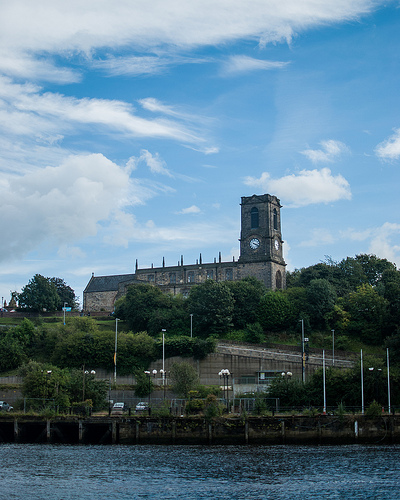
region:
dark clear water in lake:
[159, 452, 306, 498]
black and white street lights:
[212, 364, 236, 420]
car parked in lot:
[108, 397, 128, 412]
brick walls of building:
[252, 258, 269, 274]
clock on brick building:
[245, 232, 266, 257]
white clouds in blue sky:
[51, 100, 158, 212]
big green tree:
[14, 272, 79, 322]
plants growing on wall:
[96, 345, 140, 390]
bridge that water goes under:
[37, 418, 126, 472]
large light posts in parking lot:
[293, 309, 315, 412]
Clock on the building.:
[243, 232, 264, 252]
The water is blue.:
[63, 453, 363, 497]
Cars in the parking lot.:
[103, 394, 165, 414]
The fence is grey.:
[27, 392, 281, 415]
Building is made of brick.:
[80, 194, 302, 303]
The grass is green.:
[8, 312, 127, 333]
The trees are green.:
[132, 264, 394, 341]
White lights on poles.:
[212, 365, 236, 381]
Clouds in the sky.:
[20, 162, 119, 257]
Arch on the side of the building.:
[271, 267, 287, 293]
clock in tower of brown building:
[243, 235, 264, 253]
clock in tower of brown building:
[266, 238, 283, 256]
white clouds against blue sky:
[10, 5, 86, 66]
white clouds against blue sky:
[10, 96, 98, 146]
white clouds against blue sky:
[24, 209, 131, 257]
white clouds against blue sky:
[118, 194, 202, 244]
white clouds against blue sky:
[305, 184, 370, 244]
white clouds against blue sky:
[119, 165, 208, 208]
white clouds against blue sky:
[91, 44, 231, 125]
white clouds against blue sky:
[196, 28, 366, 109]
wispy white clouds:
[0, 1, 398, 67]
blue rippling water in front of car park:
[1, 441, 398, 498]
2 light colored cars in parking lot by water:
[112, 399, 149, 412]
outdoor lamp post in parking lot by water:
[216, 368, 237, 412]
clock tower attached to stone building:
[239, 197, 283, 263]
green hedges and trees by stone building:
[127, 283, 396, 325]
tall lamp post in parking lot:
[162, 327, 166, 402]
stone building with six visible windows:
[84, 256, 285, 308]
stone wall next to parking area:
[154, 355, 320, 382]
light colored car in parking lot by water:
[0, 397, 14, 409]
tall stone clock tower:
[237, 189, 285, 272]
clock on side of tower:
[241, 231, 266, 258]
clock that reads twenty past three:
[244, 232, 263, 254]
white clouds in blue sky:
[2, 83, 392, 279]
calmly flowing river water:
[5, 423, 397, 499]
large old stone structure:
[64, 189, 309, 318]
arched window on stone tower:
[247, 204, 263, 233]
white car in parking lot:
[133, 397, 153, 416]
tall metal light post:
[154, 323, 172, 393]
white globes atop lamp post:
[211, 367, 234, 382]